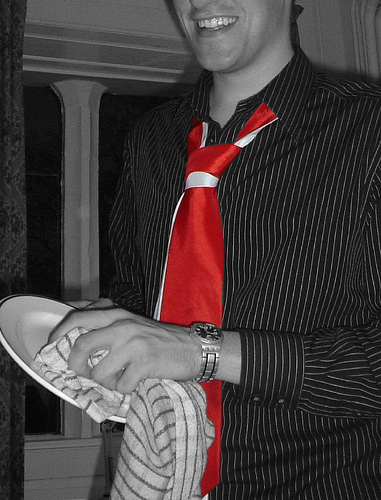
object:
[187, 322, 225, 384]
watch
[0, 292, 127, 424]
plate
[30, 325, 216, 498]
rag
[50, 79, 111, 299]
post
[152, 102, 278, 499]
tie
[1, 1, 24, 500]
curtain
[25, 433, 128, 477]
sill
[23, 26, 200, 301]
window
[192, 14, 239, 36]
mouth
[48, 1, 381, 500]
man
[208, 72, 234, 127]
neck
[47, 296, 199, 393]
hand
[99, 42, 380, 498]
shirt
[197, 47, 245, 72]
chin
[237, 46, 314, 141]
collar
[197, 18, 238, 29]
teeth